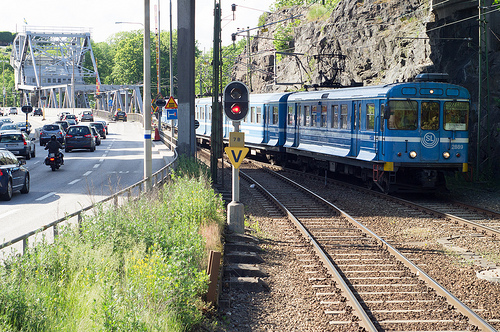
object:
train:
[160, 81, 470, 196]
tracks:
[243, 155, 500, 240]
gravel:
[273, 264, 288, 275]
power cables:
[219, 0, 496, 88]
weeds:
[13, 265, 27, 302]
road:
[0, 112, 169, 267]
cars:
[63, 125, 98, 153]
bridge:
[10, 23, 145, 115]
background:
[0, 0, 500, 115]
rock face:
[233, 2, 494, 85]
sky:
[0, 0, 276, 58]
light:
[230, 103, 243, 116]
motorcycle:
[44, 143, 68, 172]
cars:
[0, 132, 37, 160]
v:
[230, 148, 244, 163]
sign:
[223, 146, 249, 169]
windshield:
[387, 100, 419, 131]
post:
[203, 250, 222, 312]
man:
[45, 134, 61, 154]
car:
[1, 149, 31, 201]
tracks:
[204, 147, 499, 332]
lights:
[407, 151, 419, 160]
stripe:
[249, 124, 467, 149]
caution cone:
[152, 127, 162, 141]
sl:
[421, 132, 439, 147]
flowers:
[136, 259, 151, 272]